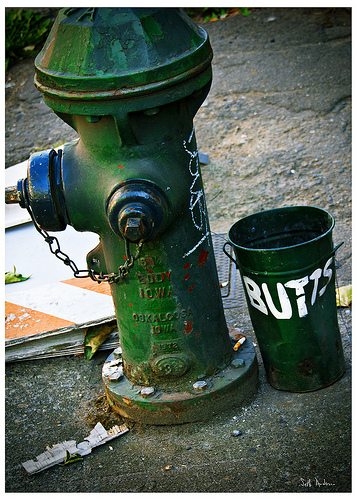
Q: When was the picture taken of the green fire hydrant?
A: Early morning.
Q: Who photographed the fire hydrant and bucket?
A: Business owner.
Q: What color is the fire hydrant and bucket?
A: Green.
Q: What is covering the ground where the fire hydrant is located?
A: Asphalt.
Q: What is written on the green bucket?
A: BUTTS.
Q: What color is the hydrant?
A: Green.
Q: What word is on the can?
A: Butts.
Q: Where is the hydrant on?
A: The street.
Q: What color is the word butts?
A: White.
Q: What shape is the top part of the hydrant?
A: Octagon.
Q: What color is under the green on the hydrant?
A: Red.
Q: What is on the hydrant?
A: A Chain.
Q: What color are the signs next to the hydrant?
A: Orange and White.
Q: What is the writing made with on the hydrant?
A: Chalk.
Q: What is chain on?
A: Fire hydrant.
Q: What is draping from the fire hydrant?
A: A chain.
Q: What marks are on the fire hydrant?
A: Reddish brown rust.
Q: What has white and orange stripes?
A: Construction stand.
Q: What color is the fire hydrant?
A: Green.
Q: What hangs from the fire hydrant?
A: The chain.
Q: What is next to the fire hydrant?
A: Green bucket.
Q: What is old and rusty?
A: The fire hydrant.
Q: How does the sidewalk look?
A: Very old.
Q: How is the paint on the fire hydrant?
A: Peeling off.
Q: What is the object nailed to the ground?
A: Fire hydrant.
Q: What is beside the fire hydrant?
A: Bucket.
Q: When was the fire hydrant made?
A: 1978.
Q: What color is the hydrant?
A: Blue-green.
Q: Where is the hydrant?
A: In concrete.